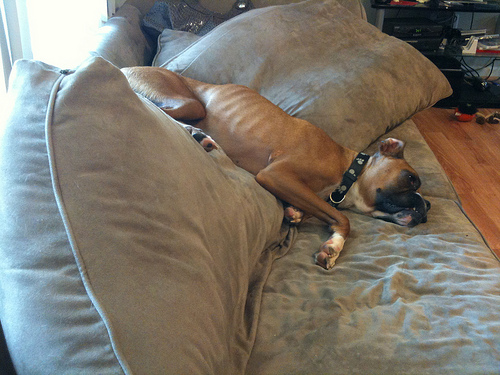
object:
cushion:
[155, 0, 454, 151]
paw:
[315, 244, 333, 270]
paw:
[284, 207, 301, 224]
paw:
[207, 140, 219, 151]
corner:
[437, 81, 453, 97]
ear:
[380, 137, 406, 159]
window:
[20, 0, 106, 69]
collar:
[326, 152, 370, 209]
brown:
[472, 136, 498, 228]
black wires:
[455, 56, 480, 77]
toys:
[454, 105, 479, 121]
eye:
[408, 174, 414, 184]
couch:
[0, 1, 499, 373]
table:
[417, 51, 499, 61]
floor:
[411, 105, 500, 252]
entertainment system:
[373, 8, 463, 109]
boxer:
[118, 65, 430, 270]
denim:
[138, 0, 254, 35]